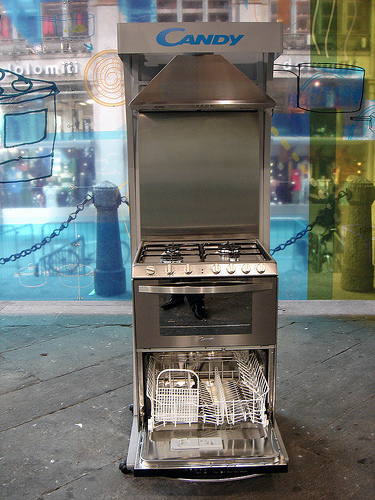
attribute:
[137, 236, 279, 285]
stove — gas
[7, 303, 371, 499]
floor — grey, stone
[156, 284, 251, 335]
window — glass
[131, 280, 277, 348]
door — steel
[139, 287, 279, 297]
handle — long, silver, metal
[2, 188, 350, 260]
chain — black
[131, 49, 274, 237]
hood — steel